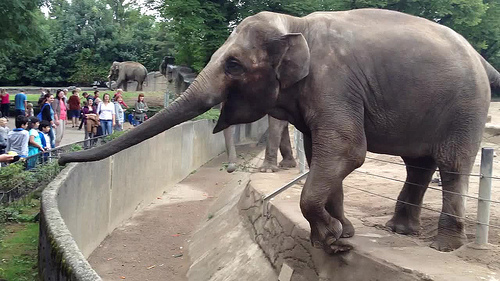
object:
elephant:
[60, 9, 500, 256]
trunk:
[57, 70, 218, 167]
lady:
[53, 89, 71, 149]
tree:
[0, 0, 60, 83]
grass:
[1, 92, 224, 281]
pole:
[475, 147, 495, 250]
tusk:
[107, 73, 112, 80]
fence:
[223, 123, 500, 250]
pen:
[40, 104, 499, 280]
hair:
[14, 115, 29, 129]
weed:
[37, 198, 81, 280]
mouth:
[213, 98, 268, 134]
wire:
[295, 162, 499, 229]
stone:
[236, 169, 425, 280]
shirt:
[96, 99, 118, 121]